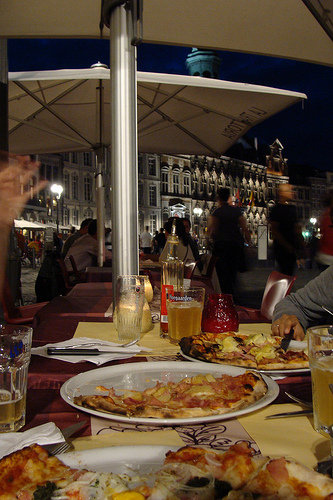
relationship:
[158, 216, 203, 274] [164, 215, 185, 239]
people has head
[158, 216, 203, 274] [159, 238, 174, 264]
people has arms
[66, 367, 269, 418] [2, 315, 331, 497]
pizza on table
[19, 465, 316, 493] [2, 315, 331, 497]
cheese pizza on table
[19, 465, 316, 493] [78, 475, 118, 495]
cheese pizza has cheese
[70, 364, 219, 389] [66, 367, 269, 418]
plate has pizza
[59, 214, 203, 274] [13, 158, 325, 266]
people are in background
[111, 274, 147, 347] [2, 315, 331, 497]
glass on table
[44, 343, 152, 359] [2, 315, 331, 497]
knife on table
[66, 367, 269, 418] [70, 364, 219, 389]
pizza on plate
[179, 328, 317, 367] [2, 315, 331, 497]
almost whole pizza on table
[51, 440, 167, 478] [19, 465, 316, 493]
piece gone from cheese pizza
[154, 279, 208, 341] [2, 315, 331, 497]
beer on table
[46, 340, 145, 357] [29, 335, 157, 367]
fork and knife on napkin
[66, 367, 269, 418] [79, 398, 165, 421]
pizza has crust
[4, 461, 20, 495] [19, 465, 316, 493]
tomato sauce on cheese pizza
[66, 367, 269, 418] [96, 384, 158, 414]
pizza in pieces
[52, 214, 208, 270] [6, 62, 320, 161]
diners are under umbrella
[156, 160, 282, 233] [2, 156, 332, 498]
building faces restaurant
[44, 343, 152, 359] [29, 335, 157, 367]
knife on napkin